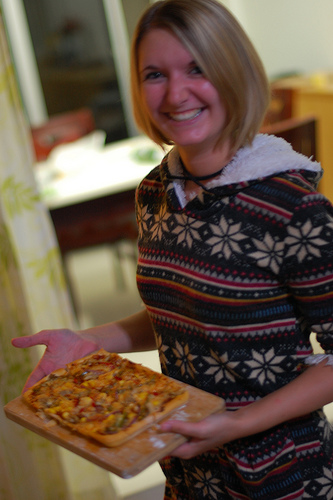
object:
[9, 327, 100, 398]
hand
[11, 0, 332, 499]
woman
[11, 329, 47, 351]
thumb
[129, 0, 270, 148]
head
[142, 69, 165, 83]
eye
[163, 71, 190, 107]
nose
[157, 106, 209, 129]
mouth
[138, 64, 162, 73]
eyebrow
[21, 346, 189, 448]
pizza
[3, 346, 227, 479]
tray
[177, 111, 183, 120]
teeth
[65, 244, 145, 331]
floor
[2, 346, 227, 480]
board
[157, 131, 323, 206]
hood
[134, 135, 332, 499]
dress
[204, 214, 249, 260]
pattern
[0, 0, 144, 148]
doorway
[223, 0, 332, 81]
wall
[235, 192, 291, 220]
stripe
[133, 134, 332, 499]
sweater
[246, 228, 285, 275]
snowflake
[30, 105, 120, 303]
chairs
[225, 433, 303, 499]
pockets